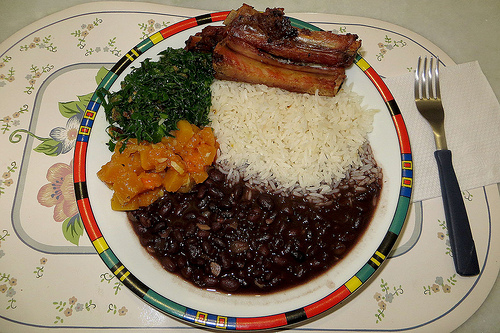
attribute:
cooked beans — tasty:
[141, 210, 350, 269]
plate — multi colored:
[106, 7, 413, 329]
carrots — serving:
[97, 123, 229, 209]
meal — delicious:
[98, 3, 383, 295]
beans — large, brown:
[114, 169, 382, 296]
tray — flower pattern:
[13, 3, 487, 308]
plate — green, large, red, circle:
[70, 6, 417, 331]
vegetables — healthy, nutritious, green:
[92, 61, 229, 141]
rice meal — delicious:
[211, 113, 339, 194]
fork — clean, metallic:
[415, 57, 485, 283]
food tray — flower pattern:
[404, 272, 435, 332]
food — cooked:
[97, 4, 390, 299]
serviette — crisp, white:
[378, 58, 498, 200]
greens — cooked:
[113, 69, 213, 144]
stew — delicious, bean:
[138, 156, 375, 293]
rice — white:
[204, 79, 375, 194]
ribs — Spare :
[191, 0, 363, 92]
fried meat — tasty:
[219, 2, 361, 69]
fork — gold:
[413, 50, 480, 277]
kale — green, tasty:
[98, 46, 211, 140]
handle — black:
[435, 147, 481, 282]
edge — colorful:
[72, 118, 100, 235]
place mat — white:
[0, 6, 79, 328]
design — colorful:
[27, 69, 72, 250]